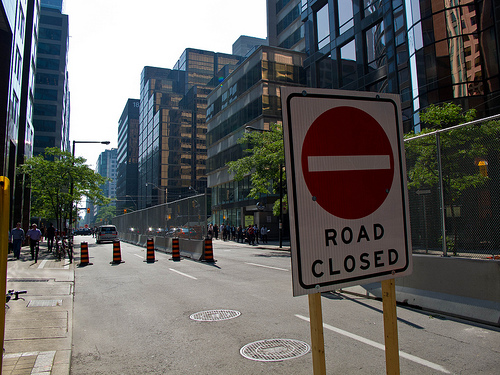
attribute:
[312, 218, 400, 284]
writing — black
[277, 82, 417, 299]
sign — white, red, black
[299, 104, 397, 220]
circle — red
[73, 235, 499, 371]
street — paved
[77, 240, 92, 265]
cone — red, black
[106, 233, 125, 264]
cone — black, red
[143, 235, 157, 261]
cone — red, black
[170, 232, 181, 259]
cone — black, red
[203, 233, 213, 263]
cone — red, black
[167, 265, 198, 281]
lane marker — white, painted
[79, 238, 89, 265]
cone — striped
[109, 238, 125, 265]
cone — striped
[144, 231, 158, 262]
cone — striped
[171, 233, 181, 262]
cone — striped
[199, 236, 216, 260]
cone — striped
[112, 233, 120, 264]
cone — orange, black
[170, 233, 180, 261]
cone — black, orange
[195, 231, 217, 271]
cone — orange, black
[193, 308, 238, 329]
cover — manhole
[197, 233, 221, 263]
barrel — black, orange, caution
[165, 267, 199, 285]
line — white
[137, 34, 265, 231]
building — tall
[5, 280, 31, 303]
handle — bicycle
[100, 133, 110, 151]
light — tall, street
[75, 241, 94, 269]
pylons — orange, black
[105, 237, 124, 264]
pylons — orange, black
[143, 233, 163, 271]
pylons — orange, black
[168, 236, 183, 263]
pylons — orange, black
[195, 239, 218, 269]
pylons — orange, black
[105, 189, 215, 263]
fence — metal, chain link, large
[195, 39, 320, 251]
building — tan, multi-story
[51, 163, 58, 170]
leaves — green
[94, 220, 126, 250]
car — silver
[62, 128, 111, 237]
lamp — street